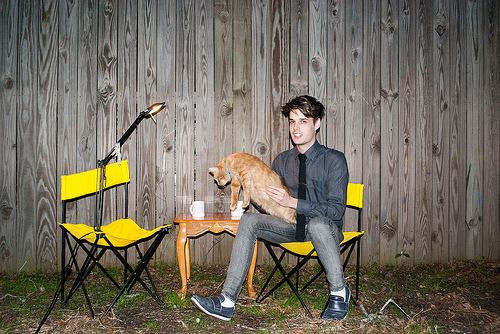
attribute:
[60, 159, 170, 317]
chair — yellow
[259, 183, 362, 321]
chair — yellow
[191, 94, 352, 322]
man — young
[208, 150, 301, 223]
cat — brown, orange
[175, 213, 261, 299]
table — brown, small, wooden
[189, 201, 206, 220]
cup — white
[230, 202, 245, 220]
cup — white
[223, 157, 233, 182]
collar — blue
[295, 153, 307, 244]
tie — black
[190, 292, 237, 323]
shoe — blue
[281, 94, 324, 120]
hair — black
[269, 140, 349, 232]
shirt — gray, blue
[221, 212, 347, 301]
jeans — denim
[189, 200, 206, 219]
mug — white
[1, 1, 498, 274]
fence — wooden, long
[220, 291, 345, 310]
socks — white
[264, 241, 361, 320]
base — black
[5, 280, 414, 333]
twigs — broken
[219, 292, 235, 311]
sock — white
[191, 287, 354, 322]
loafers — blue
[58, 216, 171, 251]
seat — yellow